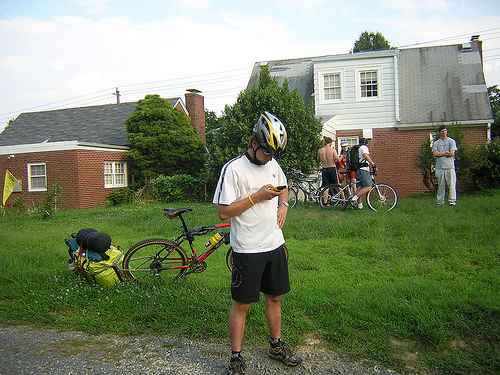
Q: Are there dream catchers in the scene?
A: No, there are no dream catchers.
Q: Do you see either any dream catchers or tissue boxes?
A: No, there are no dream catchers or tissue boxes.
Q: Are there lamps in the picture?
A: No, there are no lamps.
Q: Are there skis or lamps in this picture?
A: No, there are no lamps or skis.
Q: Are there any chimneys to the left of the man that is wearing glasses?
A: Yes, there is a chimney to the left of the man.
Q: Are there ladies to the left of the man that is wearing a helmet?
A: No, there is a chimney to the left of the man.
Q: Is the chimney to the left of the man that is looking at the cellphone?
A: Yes, the chimney is to the left of the man.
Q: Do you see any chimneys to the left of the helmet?
A: Yes, there is a chimney to the left of the helmet.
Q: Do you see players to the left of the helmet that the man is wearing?
A: No, there is a chimney to the left of the helmet.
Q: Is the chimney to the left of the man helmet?
A: Yes, the chimney is to the left of the helmet.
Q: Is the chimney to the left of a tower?
A: No, the chimney is to the left of the helmet.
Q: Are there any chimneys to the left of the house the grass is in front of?
A: Yes, there is a chimney to the left of the house.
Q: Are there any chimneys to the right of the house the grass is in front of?
A: No, the chimney is to the left of the house.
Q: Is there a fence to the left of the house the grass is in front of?
A: No, there is a chimney to the left of the house.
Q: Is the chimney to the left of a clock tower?
A: No, the chimney is to the left of the house.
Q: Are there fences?
A: No, there are no fences.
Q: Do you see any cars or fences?
A: No, there are no fences or cars.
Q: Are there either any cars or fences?
A: No, there are no fences or cars.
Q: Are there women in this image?
A: No, there are no women.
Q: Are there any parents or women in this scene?
A: No, there are no women or parents.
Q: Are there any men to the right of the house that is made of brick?
A: Yes, there is a man to the right of the house.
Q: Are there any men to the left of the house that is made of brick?
A: No, the man is to the right of the house.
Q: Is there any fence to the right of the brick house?
A: No, there is a man to the right of the house.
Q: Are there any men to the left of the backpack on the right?
A: Yes, there is a man to the left of the backpack.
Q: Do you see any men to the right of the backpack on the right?
A: No, the man is to the left of the backpack.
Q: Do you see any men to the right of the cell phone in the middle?
A: Yes, there is a man to the right of the cellphone.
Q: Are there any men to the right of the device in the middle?
A: Yes, there is a man to the right of the cellphone.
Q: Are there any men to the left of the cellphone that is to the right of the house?
A: No, the man is to the right of the cell phone.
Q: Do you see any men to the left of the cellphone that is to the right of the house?
A: No, the man is to the right of the cell phone.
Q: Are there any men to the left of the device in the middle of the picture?
A: No, the man is to the right of the cell phone.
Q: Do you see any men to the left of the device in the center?
A: No, the man is to the right of the cell phone.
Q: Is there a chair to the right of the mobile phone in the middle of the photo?
A: No, there is a man to the right of the cellphone.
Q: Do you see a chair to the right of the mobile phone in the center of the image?
A: No, there is a man to the right of the cellphone.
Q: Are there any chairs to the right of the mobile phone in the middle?
A: No, there is a man to the right of the cellphone.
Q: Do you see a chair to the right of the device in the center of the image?
A: No, there is a man to the right of the cellphone.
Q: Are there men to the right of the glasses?
A: Yes, there is a man to the right of the glasses.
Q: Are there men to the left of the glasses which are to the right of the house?
A: No, the man is to the right of the glasses.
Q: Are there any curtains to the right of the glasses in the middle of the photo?
A: No, there is a man to the right of the glasses.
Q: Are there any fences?
A: No, there are no fences.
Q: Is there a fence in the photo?
A: No, there are no fences.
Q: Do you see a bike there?
A: Yes, there is a bike.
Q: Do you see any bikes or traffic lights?
A: Yes, there is a bike.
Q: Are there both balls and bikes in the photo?
A: No, there is a bike but no balls.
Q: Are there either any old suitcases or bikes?
A: Yes, there is an old bike.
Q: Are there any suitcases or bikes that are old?
A: Yes, the bike is old.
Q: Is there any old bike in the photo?
A: Yes, there is an old bike.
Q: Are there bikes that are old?
A: Yes, there is a bike that is old.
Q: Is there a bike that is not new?
A: Yes, there is a old bike.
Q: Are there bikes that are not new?
A: Yes, there is a old bike.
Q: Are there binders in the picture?
A: No, there are no binders.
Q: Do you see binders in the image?
A: No, there are no binders.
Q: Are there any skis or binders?
A: No, there are no binders or skis.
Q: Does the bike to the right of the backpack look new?
A: No, the bike is old.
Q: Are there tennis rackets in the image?
A: No, there are no tennis rackets.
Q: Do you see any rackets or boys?
A: No, there are no rackets or boys.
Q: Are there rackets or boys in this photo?
A: No, there are no rackets or boys.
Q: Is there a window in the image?
A: Yes, there is a window.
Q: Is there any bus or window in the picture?
A: Yes, there is a window.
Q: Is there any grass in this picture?
A: Yes, there is grass.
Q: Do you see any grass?
A: Yes, there is grass.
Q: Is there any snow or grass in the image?
A: Yes, there is grass.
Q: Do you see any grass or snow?
A: Yes, there is grass.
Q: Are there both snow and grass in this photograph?
A: No, there is grass but no snow.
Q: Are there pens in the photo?
A: No, there are no pens.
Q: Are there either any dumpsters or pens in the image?
A: No, there are no pens or dumpsters.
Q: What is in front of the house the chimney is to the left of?
A: The grass is in front of the house.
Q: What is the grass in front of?
A: The grass is in front of the house.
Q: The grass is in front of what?
A: The grass is in front of the house.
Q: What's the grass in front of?
A: The grass is in front of the house.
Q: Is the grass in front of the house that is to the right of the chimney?
A: Yes, the grass is in front of the house.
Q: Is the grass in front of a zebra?
A: No, the grass is in front of the house.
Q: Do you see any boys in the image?
A: No, there are no boys.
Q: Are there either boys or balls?
A: No, there are no boys or balls.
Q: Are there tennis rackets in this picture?
A: No, there are no tennis rackets.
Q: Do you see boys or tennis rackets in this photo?
A: No, there are no tennis rackets or boys.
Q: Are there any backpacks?
A: Yes, there is a backpack.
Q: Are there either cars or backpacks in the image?
A: Yes, there is a backpack.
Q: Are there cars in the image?
A: No, there are no cars.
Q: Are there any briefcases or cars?
A: No, there are no cars or briefcases.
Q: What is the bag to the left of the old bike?
A: The bag is a backpack.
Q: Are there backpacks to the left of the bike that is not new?
A: Yes, there is a backpack to the left of the bike.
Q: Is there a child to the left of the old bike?
A: No, there is a backpack to the left of the bike.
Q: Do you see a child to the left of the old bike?
A: No, there is a backpack to the left of the bike.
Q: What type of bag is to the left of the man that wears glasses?
A: The bag is a backpack.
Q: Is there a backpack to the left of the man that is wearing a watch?
A: Yes, there is a backpack to the left of the man.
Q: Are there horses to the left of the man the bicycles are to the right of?
A: No, there is a backpack to the left of the man.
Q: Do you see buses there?
A: No, there are no buses.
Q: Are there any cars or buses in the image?
A: No, there are no buses or cars.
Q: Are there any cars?
A: No, there are no cars.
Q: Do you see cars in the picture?
A: No, there are no cars.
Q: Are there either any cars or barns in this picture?
A: No, there are no cars or barns.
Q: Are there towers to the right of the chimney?
A: No, there is a house to the right of the chimney.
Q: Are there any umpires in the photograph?
A: No, there are no umpires.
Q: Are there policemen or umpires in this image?
A: No, there are no umpires or policemen.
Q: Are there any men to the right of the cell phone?
A: Yes, there are men to the right of the cell phone.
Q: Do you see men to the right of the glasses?
A: Yes, there are men to the right of the glasses.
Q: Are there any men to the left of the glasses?
A: No, the men are to the right of the glasses.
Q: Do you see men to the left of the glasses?
A: No, the men are to the right of the glasses.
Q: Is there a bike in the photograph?
A: Yes, there are bikes.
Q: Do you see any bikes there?
A: Yes, there are bikes.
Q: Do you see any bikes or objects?
A: Yes, there are bikes.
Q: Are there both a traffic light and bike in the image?
A: No, there are bikes but no traffic lights.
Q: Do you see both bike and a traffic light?
A: No, there are bikes but no traffic lights.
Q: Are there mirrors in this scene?
A: No, there are no mirrors.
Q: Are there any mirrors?
A: No, there are no mirrors.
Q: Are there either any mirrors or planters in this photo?
A: No, there are no mirrors or planters.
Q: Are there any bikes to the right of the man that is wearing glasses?
A: Yes, there are bikes to the right of the man.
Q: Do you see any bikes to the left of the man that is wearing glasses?
A: No, the bikes are to the right of the man.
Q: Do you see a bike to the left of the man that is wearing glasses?
A: No, the bikes are to the right of the man.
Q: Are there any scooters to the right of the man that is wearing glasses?
A: No, there are bikes to the right of the man.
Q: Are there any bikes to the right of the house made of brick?
A: Yes, there are bikes to the right of the house.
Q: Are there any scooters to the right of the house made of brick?
A: No, there are bikes to the right of the house.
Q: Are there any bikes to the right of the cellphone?
A: Yes, there are bikes to the right of the cellphone.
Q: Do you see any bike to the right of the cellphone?
A: Yes, there are bikes to the right of the cellphone.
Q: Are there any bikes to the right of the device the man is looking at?
A: Yes, there are bikes to the right of the cellphone.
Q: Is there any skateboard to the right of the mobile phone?
A: No, there are bikes to the right of the mobile phone.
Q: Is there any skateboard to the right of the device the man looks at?
A: No, there are bikes to the right of the mobile phone.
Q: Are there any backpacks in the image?
A: Yes, there is a backpack.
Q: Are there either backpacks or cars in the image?
A: Yes, there is a backpack.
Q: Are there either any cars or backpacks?
A: Yes, there is a backpack.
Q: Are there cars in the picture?
A: No, there are no cars.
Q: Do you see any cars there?
A: No, there are no cars.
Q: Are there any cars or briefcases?
A: No, there are no cars or briefcases.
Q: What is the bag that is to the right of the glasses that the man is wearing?
A: The bag is a backpack.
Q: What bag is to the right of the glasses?
A: The bag is a backpack.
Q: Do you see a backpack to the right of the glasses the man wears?
A: Yes, there is a backpack to the right of the glasses.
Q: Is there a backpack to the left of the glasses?
A: No, the backpack is to the right of the glasses.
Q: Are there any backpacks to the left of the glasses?
A: No, the backpack is to the right of the glasses.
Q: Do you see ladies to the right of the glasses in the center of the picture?
A: No, there is a backpack to the right of the glasses.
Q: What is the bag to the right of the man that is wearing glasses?
A: The bag is a backpack.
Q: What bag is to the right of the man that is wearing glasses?
A: The bag is a backpack.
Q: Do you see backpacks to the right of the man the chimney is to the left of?
A: Yes, there is a backpack to the right of the man.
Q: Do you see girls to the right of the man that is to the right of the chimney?
A: No, there is a backpack to the right of the man.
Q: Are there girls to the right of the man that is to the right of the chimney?
A: No, there is a backpack to the right of the man.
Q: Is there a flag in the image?
A: Yes, there is a flag.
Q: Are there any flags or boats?
A: Yes, there is a flag.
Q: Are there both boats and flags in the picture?
A: No, there is a flag but no boats.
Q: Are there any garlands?
A: No, there are no garlands.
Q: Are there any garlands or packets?
A: No, there are no garlands or packets.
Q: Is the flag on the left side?
A: Yes, the flag is on the left of the image.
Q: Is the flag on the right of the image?
A: No, the flag is on the left of the image.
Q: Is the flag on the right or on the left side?
A: The flag is on the left of the image.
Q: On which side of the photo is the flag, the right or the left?
A: The flag is on the left of the image.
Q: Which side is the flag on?
A: The flag is on the left of the image.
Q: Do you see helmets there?
A: Yes, there is a helmet.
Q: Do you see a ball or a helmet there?
A: Yes, there is a helmet.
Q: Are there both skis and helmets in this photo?
A: No, there is a helmet but no skis.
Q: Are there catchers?
A: No, there are no catchers.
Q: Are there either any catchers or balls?
A: No, there are no catchers or balls.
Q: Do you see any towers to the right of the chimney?
A: No, there is a helmet to the right of the chimney.